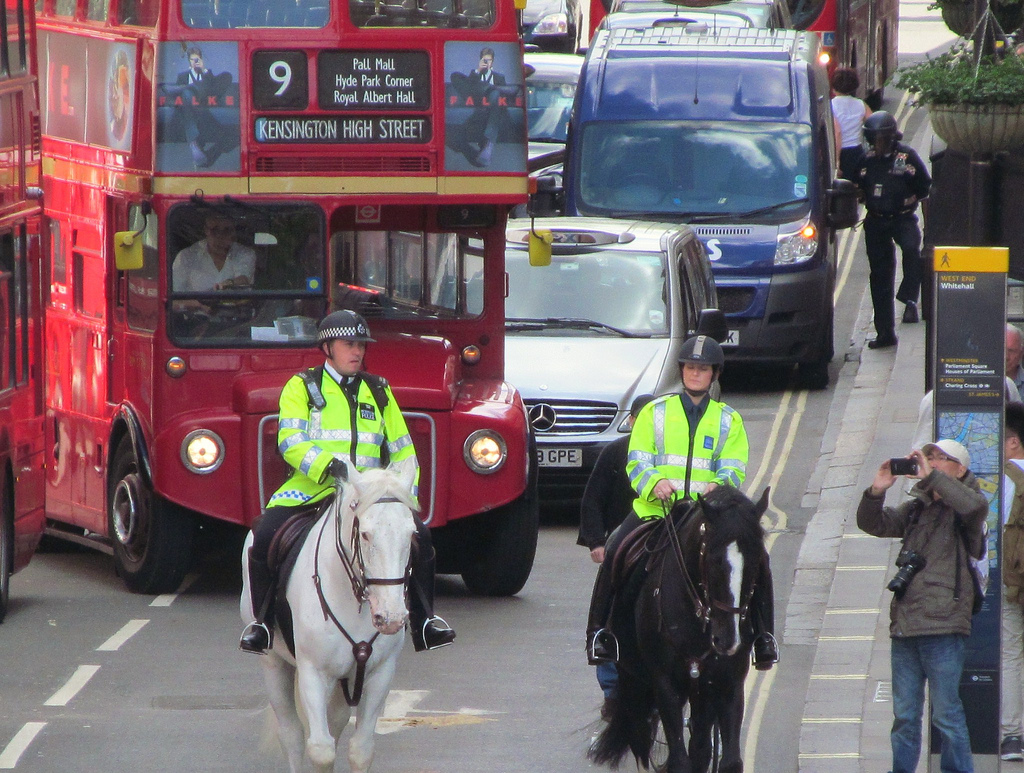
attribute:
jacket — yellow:
[269, 364, 432, 513]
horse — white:
[217, 479, 455, 771]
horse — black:
[554, 483, 804, 766]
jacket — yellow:
[612, 379, 764, 512]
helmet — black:
[299, 294, 375, 343]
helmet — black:
[662, 328, 729, 374]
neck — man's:
[921, 477, 956, 504]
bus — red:
[17, 2, 536, 595]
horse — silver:
[210, 460, 457, 758]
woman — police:
[582, 332, 798, 681]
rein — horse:
[310, 498, 386, 704]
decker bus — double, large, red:
[32, 8, 561, 615]